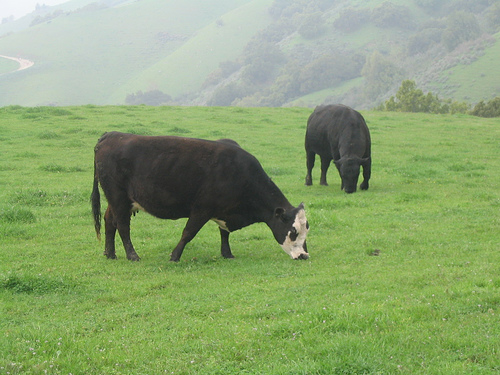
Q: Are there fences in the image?
A: No, there are no fences.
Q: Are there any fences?
A: No, there are no fences.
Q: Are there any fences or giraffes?
A: No, there are no fences or giraffes.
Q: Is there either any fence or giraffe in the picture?
A: No, there are no fences or giraffes.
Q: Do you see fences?
A: No, there are no fences.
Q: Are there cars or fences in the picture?
A: No, there are no fences or cars.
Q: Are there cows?
A: Yes, there is a cow.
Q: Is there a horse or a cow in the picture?
A: Yes, there is a cow.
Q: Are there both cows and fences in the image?
A: No, there is a cow but no fences.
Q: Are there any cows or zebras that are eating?
A: Yes, the cow is eating.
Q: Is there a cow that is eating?
A: Yes, there is a cow that is eating.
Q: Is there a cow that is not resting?
A: Yes, there is a cow that is eating.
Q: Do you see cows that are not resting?
A: Yes, there is a cow that is eating .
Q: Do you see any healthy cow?
A: Yes, there is a healthy cow.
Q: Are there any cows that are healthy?
A: Yes, there is a cow that is healthy.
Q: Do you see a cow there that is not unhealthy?
A: Yes, there is an healthy cow.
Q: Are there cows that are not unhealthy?
A: Yes, there is an healthy cow.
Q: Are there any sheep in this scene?
A: No, there are no sheep.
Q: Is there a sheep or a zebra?
A: No, there are no sheep or zebras.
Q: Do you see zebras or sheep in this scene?
A: No, there are no sheep or zebras.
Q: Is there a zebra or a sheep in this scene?
A: No, there are no sheep or zebras.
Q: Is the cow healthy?
A: Yes, the cow is healthy.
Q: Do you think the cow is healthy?
A: Yes, the cow is healthy.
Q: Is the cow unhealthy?
A: No, the cow is healthy.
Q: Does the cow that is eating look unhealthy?
A: No, the cow is healthy.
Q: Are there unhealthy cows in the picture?
A: No, there is a cow but it is healthy.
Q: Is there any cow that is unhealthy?
A: No, there is a cow but it is healthy.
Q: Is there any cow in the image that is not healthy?
A: No, there is a cow but it is healthy.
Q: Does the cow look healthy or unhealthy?
A: The cow is healthy.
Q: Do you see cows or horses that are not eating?
A: No, there is a cow but it is eating.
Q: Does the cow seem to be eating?
A: Yes, the cow is eating.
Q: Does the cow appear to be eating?
A: Yes, the cow is eating.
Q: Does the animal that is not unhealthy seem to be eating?
A: Yes, the cow is eating.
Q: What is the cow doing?
A: The cow is eating.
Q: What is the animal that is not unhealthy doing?
A: The cow is eating.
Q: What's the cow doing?
A: The cow is eating.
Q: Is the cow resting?
A: No, the cow is eating.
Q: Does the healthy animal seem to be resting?
A: No, the cow is eating.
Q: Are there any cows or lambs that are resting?
A: No, there is a cow but it is eating.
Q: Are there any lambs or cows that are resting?
A: No, there is a cow but it is eating.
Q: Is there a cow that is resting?
A: No, there is a cow but it is eating.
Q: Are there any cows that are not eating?
A: No, there is a cow but it is eating.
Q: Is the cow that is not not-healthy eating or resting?
A: The cow is eating.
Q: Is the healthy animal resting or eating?
A: The cow is eating.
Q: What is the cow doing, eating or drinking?
A: The cow is eating.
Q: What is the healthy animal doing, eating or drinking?
A: The cow is eating.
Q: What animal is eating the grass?
A: The cow is eating the grass.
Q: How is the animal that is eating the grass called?
A: The animal is a cow.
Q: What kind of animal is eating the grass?
A: The animal is a cow.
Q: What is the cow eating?
A: The cow is eating grass.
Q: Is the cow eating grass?
A: Yes, the cow is eating grass.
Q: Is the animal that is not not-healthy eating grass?
A: Yes, the cow is eating grass.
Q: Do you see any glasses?
A: No, there are no glasses.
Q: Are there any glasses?
A: No, there are no glasses.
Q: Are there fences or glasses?
A: No, there are no glasses or fences.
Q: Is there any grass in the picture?
A: Yes, there is grass.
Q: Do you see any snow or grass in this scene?
A: Yes, there is grass.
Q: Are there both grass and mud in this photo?
A: No, there is grass but no mud.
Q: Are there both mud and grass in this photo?
A: No, there is grass but no mud.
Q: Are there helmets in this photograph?
A: No, there are no helmets.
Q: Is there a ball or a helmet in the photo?
A: No, there are no helmets or balls.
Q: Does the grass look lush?
A: Yes, the grass is lush.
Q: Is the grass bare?
A: No, the grass is lush.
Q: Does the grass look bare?
A: No, the grass is lush.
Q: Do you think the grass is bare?
A: No, the grass is lush.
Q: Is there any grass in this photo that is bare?
A: No, there is grass but it is lush.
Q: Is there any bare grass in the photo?
A: No, there is grass but it is lush.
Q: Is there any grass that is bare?
A: No, there is grass but it is lush.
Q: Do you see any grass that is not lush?
A: No, there is grass but it is lush.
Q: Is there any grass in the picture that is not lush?
A: No, there is grass but it is lush.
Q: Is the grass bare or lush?
A: The grass is lush.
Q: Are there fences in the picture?
A: No, there are no fences.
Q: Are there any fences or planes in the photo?
A: No, there are no fences or planes.